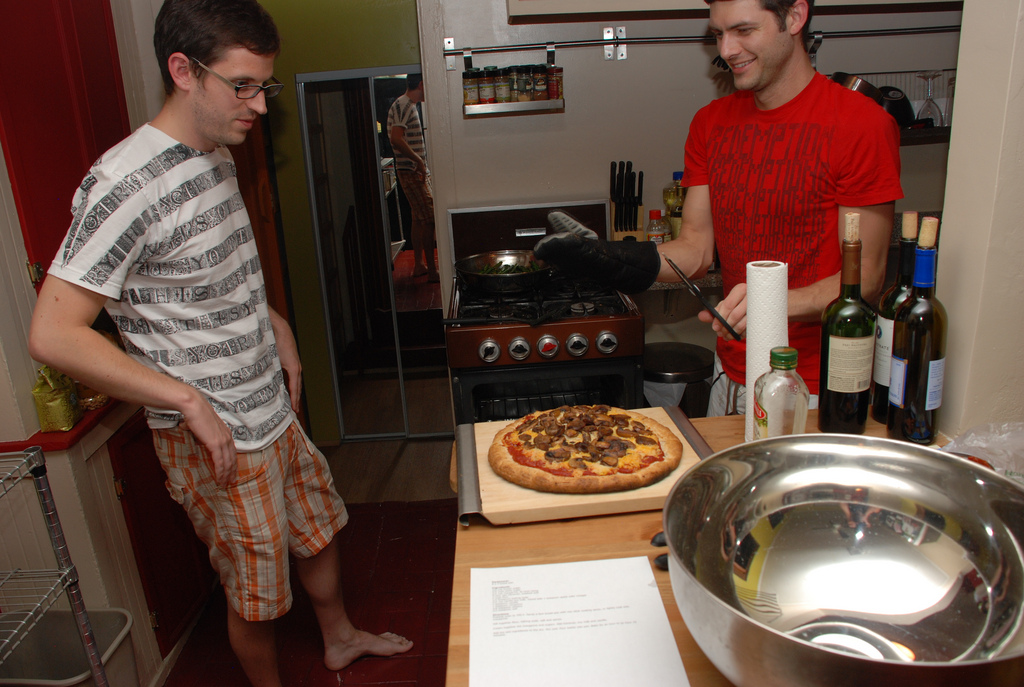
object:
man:
[532, 0, 902, 417]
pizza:
[488, 404, 683, 493]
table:
[455, 510, 663, 562]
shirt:
[681, 72, 906, 395]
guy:
[28, 0, 412, 687]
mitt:
[532, 209, 660, 295]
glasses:
[191, 57, 284, 99]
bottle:
[818, 240, 876, 434]